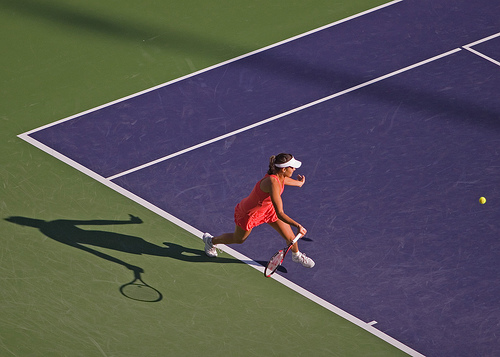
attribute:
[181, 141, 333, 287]
woman — wearing, playing, shadowed, running, hitting, female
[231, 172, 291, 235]
dress — sleeveless, pink, red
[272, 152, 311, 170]
sun visor — white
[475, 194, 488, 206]
ball — yellow, small, flying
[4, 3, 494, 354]
court — purple, blue, green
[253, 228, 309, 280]
racket — red, white, present, black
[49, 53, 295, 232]
lines — white, long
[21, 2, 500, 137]
shadow — present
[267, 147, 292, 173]
hair — pony tailed, brown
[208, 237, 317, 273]
shoes — white, tennis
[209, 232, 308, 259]
socks — white